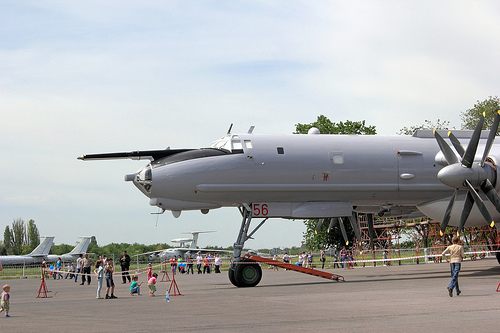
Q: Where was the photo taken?
A: An airfield.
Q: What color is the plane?
A: Gray.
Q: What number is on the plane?
A: 56.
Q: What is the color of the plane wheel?
A: Black.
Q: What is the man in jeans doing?
A: Running.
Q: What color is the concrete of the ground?
A: Gray.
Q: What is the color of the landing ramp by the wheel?
A: Red.